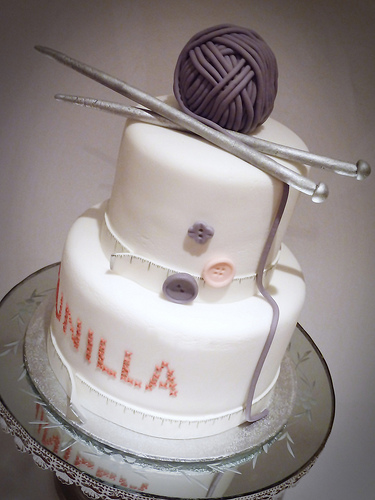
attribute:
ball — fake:
[180, 41, 267, 99]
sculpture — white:
[33, 101, 318, 352]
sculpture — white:
[26, 105, 283, 407]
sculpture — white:
[70, 119, 290, 341]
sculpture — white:
[64, 245, 289, 444]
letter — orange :
[150, 353, 181, 412]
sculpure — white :
[41, 146, 319, 462]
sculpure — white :
[17, 121, 334, 498]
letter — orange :
[114, 342, 141, 402]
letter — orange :
[90, 341, 111, 386]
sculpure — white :
[28, 122, 305, 450]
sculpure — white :
[28, 115, 328, 458]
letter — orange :
[71, 317, 96, 372]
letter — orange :
[59, 295, 87, 361]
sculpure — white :
[33, 90, 363, 422]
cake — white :
[50, 80, 300, 415]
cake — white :
[37, 116, 362, 410]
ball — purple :
[180, 26, 289, 141]